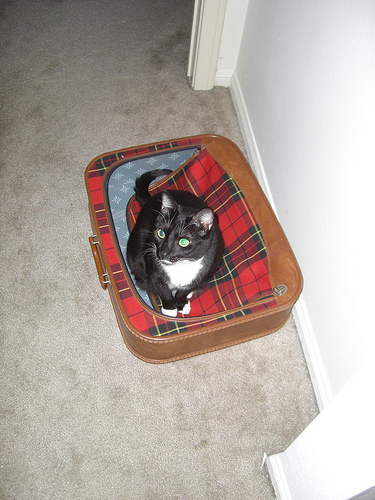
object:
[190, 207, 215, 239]
ear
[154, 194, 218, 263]
head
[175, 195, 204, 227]
hair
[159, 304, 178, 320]
paw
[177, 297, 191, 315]
paw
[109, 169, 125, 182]
design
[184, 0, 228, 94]
doorway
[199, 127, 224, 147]
zipper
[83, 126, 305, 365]
luggage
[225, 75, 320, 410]
baseboard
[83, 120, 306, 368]
plaid suitcase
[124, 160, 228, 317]
cat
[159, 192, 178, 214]
ear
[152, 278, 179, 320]
leg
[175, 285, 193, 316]
leg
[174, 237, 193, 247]
eye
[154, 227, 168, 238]
eye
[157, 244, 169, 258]
nose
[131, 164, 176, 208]
tail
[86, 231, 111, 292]
handle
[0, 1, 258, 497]
carpet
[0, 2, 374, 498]
room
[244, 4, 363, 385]
wall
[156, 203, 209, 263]
face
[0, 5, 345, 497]
floor